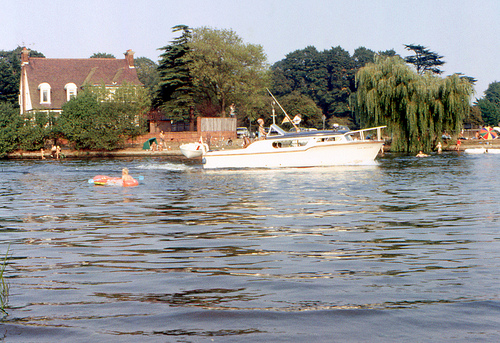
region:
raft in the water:
[81, 162, 148, 200]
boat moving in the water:
[214, 124, 401, 213]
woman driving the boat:
[236, 97, 292, 145]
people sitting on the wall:
[40, 137, 89, 171]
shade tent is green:
[139, 122, 167, 157]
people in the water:
[393, 131, 498, 168]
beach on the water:
[471, 138, 494, 167]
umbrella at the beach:
[467, 114, 498, 140]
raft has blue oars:
[83, 160, 170, 185]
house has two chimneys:
[17, 39, 172, 87]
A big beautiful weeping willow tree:
[351, 43, 482, 156]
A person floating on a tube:
[84, 159, 146, 194]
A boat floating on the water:
[197, 87, 388, 171]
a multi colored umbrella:
[476, 122, 498, 146]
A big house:
[15, 41, 145, 142]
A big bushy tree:
[153, 18, 268, 135]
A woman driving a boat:
[252, 113, 271, 141]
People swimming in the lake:
[408, 133, 448, 162]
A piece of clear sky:
[250, 0, 499, 42]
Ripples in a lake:
[156, 174, 498, 341]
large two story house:
[14, 42, 159, 133]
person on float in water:
[90, 156, 150, 194]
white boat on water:
[184, 81, 396, 178]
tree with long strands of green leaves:
[346, 44, 481, 166]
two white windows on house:
[34, 76, 84, 105]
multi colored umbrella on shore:
[476, 126, 498, 145]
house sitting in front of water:
[14, 34, 171, 166]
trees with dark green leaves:
[277, 43, 441, 110]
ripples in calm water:
[48, 190, 498, 335]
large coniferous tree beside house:
[154, 33, 211, 137]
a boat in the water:
[125, 0, 492, 253]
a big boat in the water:
[162, 43, 417, 209]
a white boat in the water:
[169, 42, 489, 273]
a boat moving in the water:
[146, 64, 406, 225]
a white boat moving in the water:
[135, 53, 432, 253]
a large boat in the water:
[179, 52, 422, 209]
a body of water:
[200, 167, 450, 340]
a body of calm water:
[251, 211, 400, 336]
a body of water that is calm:
[165, 188, 415, 321]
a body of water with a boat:
[162, 47, 432, 239]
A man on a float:
[80, 160, 157, 188]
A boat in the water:
[187, 127, 399, 184]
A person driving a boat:
[251, 110, 273, 141]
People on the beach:
[11, 130, 178, 164]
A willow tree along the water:
[378, 60, 478, 156]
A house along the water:
[17, 49, 153, 136]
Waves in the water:
[97, 192, 417, 294]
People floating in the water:
[408, 137, 475, 166]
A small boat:
[173, 136, 211, 159]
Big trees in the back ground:
[265, 27, 458, 99]